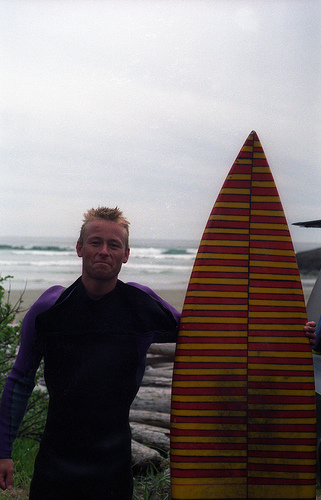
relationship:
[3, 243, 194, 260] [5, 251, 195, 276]
rocks near waves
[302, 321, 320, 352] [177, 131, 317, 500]
hand on surfboard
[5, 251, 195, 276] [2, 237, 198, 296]
waves in ocean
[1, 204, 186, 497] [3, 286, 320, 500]
man on beach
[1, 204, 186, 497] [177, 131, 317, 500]
man holding surfboard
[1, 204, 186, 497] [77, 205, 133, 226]
man has hair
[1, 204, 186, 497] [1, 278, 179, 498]
man wearing wetsuit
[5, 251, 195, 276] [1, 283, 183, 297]
waves near shore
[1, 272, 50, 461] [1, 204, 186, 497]
weeds behind man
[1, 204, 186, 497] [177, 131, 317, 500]
man with surfboard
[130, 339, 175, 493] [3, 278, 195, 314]
wood on sand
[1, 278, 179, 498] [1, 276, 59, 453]
wetsuit has sleeve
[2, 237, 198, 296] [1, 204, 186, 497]
ocean behind man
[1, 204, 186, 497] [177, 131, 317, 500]
man holds surfboard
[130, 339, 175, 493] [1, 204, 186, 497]
wood behind man